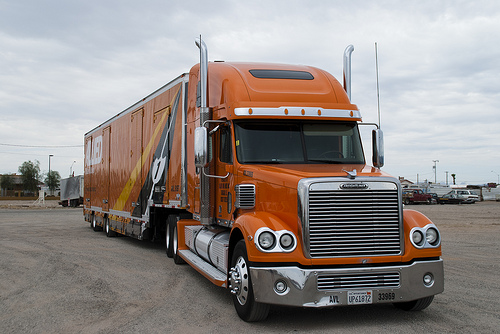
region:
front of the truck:
[166, 37, 470, 303]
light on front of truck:
[252, 216, 309, 258]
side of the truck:
[38, 74, 231, 214]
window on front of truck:
[208, 112, 372, 210]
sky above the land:
[41, 17, 143, 87]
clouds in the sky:
[8, 16, 151, 111]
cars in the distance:
[420, 177, 490, 219]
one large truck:
[26, 35, 433, 332]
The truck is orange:
[79, 60, 444, 302]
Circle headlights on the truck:
[255, 225, 298, 252]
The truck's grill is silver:
[295, 174, 405, 257]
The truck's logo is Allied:
[83, 134, 106, 166]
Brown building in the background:
[2, 173, 42, 203]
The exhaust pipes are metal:
[192, 33, 212, 109]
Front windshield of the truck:
[231, 118, 365, 165]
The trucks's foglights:
[272, 280, 290, 296]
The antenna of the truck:
[372, 39, 383, 127]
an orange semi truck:
[70, 55, 446, 325]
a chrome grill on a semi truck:
[288, 158, 410, 265]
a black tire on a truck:
[215, 230, 275, 325]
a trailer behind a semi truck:
[75, 63, 205, 244]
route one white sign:
[146, 154, 172, 185]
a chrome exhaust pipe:
[180, 19, 220, 233]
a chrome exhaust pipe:
[334, 27, 366, 157]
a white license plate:
[342, 285, 374, 304]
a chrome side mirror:
[183, 114, 223, 184]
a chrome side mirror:
[371, 122, 395, 176]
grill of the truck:
[310, 202, 396, 250]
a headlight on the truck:
[257, 227, 274, 247]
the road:
[66, 258, 145, 313]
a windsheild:
[239, 135, 358, 158]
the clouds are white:
[17, 63, 90, 109]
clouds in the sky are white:
[434, 99, 487, 148]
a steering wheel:
[322, 150, 342, 157]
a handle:
[202, 166, 216, 178]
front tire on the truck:
[226, 241, 255, 317]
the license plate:
[347, 291, 375, 311]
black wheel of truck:
[224, 240, 266, 322]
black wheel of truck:
[402, 292, 434, 313]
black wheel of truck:
[171, 218, 188, 263]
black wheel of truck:
[164, 215, 174, 252]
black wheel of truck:
[102, 213, 111, 233]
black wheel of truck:
[89, 213, 101, 229]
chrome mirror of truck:
[192, 127, 212, 168]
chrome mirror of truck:
[374, 124, 383, 168]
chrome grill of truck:
[237, 182, 255, 207]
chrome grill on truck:
[297, 175, 404, 252]